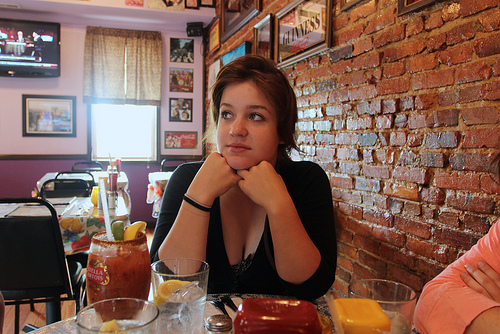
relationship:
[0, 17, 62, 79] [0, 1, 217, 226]
television on wall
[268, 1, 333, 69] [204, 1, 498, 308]
sign on wall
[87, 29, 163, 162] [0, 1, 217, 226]
window on wall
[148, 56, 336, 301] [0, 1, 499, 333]
woman in restaurant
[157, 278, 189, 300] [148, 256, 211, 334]
lemon in glass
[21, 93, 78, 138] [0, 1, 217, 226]
photo on wall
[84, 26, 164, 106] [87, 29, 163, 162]
curtain over window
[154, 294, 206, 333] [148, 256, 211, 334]
water in glass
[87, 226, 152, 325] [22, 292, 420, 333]
glass on table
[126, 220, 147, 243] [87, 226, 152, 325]
lemon on glass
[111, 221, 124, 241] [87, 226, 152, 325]
lime on glass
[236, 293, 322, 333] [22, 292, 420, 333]
bottle on table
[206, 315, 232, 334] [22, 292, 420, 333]
shaker on table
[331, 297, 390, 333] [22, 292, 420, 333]
mustard on table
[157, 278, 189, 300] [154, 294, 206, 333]
lemon in water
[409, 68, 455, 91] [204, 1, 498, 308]
brick on wall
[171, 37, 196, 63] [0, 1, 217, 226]
picture on wall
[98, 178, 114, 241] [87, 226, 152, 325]
straw in glass